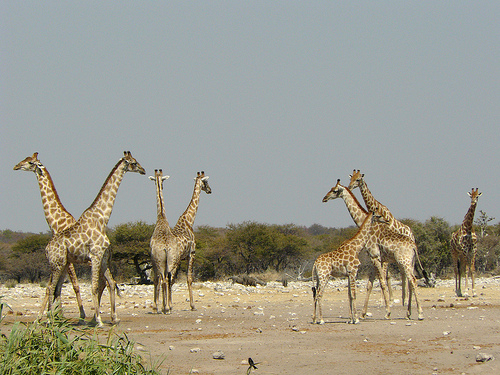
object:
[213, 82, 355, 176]
no object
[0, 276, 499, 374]
field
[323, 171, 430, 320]
giraffe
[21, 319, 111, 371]
grass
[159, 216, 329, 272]
trees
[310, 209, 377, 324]
creatures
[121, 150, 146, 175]
head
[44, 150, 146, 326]
giraffe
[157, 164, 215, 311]
giraffe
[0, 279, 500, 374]
ground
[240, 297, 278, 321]
rocks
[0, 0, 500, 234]
sky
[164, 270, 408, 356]
land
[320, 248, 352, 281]
spots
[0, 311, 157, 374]
bush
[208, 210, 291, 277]
trees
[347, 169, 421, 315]
giraffes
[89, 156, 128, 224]
neck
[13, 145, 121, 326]
giraffe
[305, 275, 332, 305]
tail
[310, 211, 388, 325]
giraffe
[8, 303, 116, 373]
foliage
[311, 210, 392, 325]
giraffe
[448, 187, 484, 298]
giraffe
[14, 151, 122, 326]
giraffe